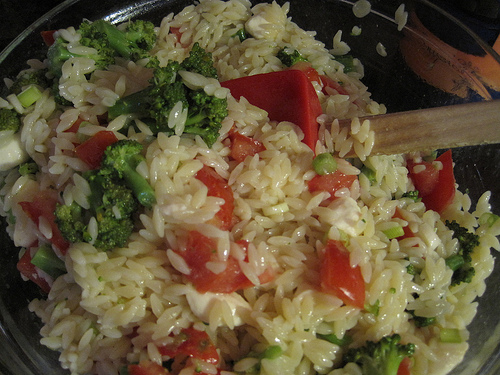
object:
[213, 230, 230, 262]
grains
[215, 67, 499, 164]
spatula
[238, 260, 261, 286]
rice grains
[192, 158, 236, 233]
pepper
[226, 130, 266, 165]
tomato piece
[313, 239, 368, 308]
tomato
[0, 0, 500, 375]
bowl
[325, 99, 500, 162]
handle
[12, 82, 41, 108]
celery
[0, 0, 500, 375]
rice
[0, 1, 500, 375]
up